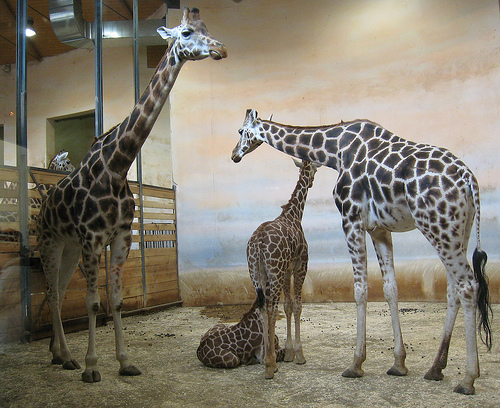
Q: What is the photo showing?
A: It is showing a pen.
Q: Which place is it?
A: It is a pen.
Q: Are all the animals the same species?
A: Yes, all the animals are giraffes.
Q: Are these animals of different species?
A: No, all the animals are giraffes.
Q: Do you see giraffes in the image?
A: Yes, there is a giraffe.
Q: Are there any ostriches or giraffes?
A: Yes, there is a giraffe.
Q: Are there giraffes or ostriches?
A: Yes, there is a giraffe.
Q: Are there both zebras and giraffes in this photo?
A: No, there is a giraffe but no zebras.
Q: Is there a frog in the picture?
A: No, there are no frogs.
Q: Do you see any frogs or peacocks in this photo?
A: No, there are no frogs or peacocks.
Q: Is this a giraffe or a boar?
A: This is a giraffe.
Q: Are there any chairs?
A: No, there are no chairs.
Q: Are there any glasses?
A: No, there are no glasses.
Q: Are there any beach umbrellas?
A: No, there are no beach umbrellas.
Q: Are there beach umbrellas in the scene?
A: No, there are no beach umbrellas.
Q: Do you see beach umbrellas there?
A: No, there are no beach umbrellas.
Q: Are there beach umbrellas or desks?
A: No, there are no beach umbrellas or desks.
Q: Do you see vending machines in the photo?
A: No, there are no vending machines.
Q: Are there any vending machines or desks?
A: No, there are no vending machines or desks.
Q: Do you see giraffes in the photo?
A: Yes, there is a giraffe.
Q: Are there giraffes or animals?
A: Yes, there is a giraffe.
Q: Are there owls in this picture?
A: No, there are no owls.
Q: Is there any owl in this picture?
A: No, there are no owls.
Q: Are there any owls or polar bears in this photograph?
A: No, there are no owls or polar bears.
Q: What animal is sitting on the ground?
A: The giraffe is sitting on the ground.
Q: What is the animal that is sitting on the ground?
A: The animal is a giraffe.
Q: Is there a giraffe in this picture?
A: Yes, there is a giraffe.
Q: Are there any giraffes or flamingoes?
A: Yes, there is a giraffe.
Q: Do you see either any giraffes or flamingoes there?
A: Yes, there is a giraffe.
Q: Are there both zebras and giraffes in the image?
A: No, there is a giraffe but no zebras.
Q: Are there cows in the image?
A: No, there are no cows.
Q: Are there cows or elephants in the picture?
A: No, there are no cows or elephants.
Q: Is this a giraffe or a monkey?
A: This is a giraffe.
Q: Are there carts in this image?
A: No, there are no carts.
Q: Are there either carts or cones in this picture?
A: No, there are no carts or cones.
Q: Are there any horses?
A: No, there are no horses.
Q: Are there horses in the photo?
A: No, there are no horses.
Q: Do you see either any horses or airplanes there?
A: No, there are no horses or airplanes.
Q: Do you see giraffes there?
A: Yes, there is a giraffe.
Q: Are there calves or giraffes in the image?
A: Yes, there is a giraffe.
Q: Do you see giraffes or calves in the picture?
A: Yes, there is a giraffe.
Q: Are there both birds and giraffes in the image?
A: No, there is a giraffe but no birds.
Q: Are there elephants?
A: No, there are no elephants.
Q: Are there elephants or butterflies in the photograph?
A: No, there are no elephants or butterflies.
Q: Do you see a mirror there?
A: No, there are no mirrors.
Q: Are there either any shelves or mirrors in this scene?
A: No, there are no mirrors or shelves.